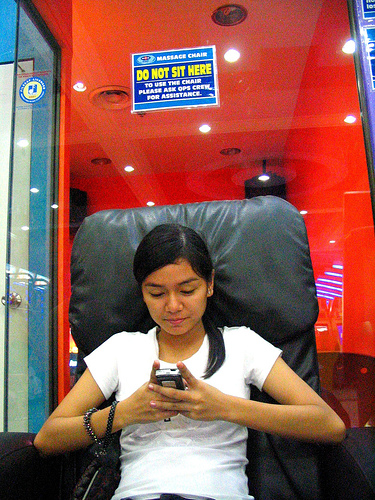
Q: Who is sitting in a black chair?
A: A girl.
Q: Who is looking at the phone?
A: The girl.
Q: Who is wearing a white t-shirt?
A: The girl.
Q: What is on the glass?
A: A blue sign.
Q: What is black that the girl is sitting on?
A: The chair.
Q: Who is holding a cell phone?
A: The girl.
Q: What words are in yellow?
A: Do Not Sit Here.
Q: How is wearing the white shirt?
A: The girl.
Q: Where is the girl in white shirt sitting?
A: On chair.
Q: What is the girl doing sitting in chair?
A: Playing on phone.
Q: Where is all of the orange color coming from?
A: Behind the girl.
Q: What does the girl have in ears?
A: Earrings.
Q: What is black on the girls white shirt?
A: Her hair.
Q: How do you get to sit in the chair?
A: Ask for assistance.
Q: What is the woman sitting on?
A: Black chair.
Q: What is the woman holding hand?
A: Cell.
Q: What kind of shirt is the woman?
A: White.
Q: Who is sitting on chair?
A: A girl.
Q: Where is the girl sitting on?
A: Black chair.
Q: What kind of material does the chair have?
A: Black leather.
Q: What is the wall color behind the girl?
A: Red.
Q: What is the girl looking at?
A: Cell phone.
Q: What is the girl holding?
A: A phone.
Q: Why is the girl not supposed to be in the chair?
A: The signs says Do Not Sit Here.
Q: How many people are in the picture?
A: One.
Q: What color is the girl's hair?
A: Black.